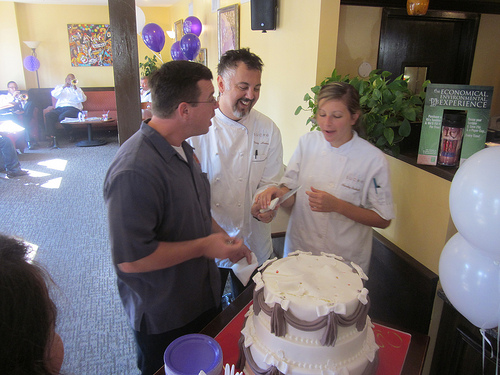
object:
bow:
[250, 272, 266, 293]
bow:
[264, 293, 293, 313]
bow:
[315, 299, 350, 320]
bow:
[355, 287, 371, 307]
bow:
[349, 258, 370, 281]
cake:
[234, 248, 378, 374]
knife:
[257, 181, 304, 216]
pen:
[372, 171, 380, 192]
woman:
[252, 82, 396, 281]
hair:
[315, 79, 364, 118]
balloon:
[141, 22, 166, 54]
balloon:
[170, 41, 195, 61]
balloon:
[182, 14, 206, 38]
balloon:
[180, 31, 201, 59]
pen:
[252, 147, 260, 163]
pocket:
[248, 153, 271, 176]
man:
[193, 46, 285, 304]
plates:
[163, 330, 224, 372]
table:
[154, 282, 435, 374]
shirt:
[274, 129, 399, 283]